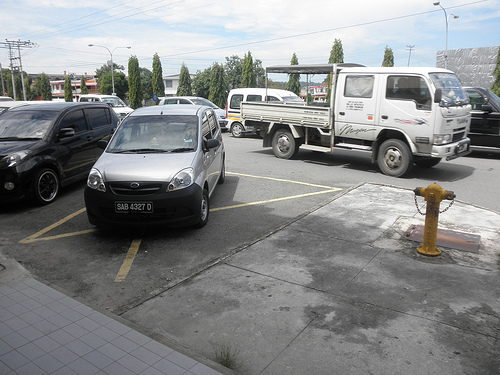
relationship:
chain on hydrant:
[415, 195, 459, 217] [411, 185, 454, 258]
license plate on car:
[118, 202, 156, 214] [83, 103, 228, 231]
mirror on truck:
[433, 89, 446, 108] [240, 66, 474, 181]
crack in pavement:
[281, 226, 380, 247] [332, 186, 403, 269]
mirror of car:
[61, 126, 75, 140] [2, 93, 119, 204]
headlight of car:
[1, 149, 29, 173] [6, 96, 117, 208]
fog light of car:
[6, 180, 15, 193] [6, 88, 111, 205]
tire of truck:
[377, 136, 411, 179] [243, 50, 470, 187]